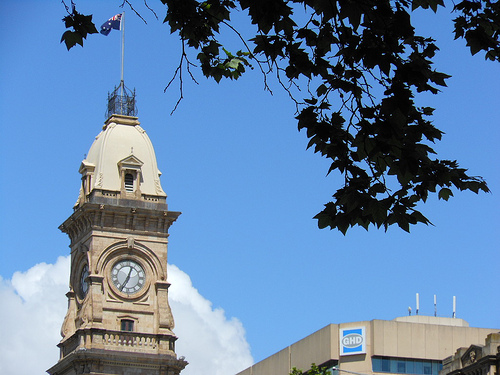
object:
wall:
[374, 326, 448, 355]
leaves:
[59, 0, 499, 236]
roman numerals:
[137, 282, 141, 287]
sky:
[228, 122, 313, 253]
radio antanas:
[391, 293, 469, 327]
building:
[235, 293, 499, 375]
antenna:
[408, 293, 456, 318]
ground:
[457, 151, 484, 183]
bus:
[108, 259, 153, 296]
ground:
[431, 151, 460, 186]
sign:
[339, 326, 366, 357]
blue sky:
[1, 0, 497, 375]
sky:
[424, 94, 481, 155]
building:
[44, 11, 189, 375]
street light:
[333, 367, 336, 371]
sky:
[194, 124, 304, 266]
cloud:
[1, 254, 255, 375]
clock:
[110, 259, 146, 295]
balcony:
[78, 328, 177, 355]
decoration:
[105, 80, 138, 120]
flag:
[100, 13, 124, 36]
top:
[105, 11, 139, 120]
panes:
[371, 357, 442, 374]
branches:
[60, 0, 500, 235]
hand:
[128, 267, 133, 276]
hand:
[118, 278, 128, 292]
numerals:
[112, 261, 144, 293]